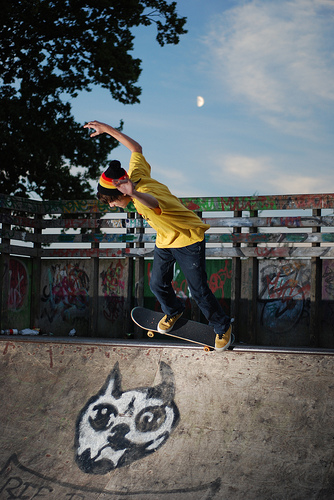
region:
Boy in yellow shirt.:
[66, 112, 253, 361]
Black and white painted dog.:
[67, 351, 201, 477]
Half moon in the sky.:
[152, 24, 287, 155]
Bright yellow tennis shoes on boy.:
[148, 293, 225, 345]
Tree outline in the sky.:
[0, 0, 186, 125]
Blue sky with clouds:
[200, 0, 324, 185]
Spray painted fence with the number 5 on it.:
[231, 174, 316, 341]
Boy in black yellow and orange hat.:
[89, 147, 137, 204]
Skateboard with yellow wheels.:
[120, 299, 151, 346]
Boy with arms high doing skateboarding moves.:
[68, 117, 247, 412]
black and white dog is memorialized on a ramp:
[69, 352, 197, 480]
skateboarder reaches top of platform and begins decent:
[74, 119, 263, 357]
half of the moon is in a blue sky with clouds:
[180, 78, 228, 140]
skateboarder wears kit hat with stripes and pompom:
[96, 148, 131, 210]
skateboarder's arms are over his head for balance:
[74, 103, 176, 238]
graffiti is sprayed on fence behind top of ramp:
[27, 185, 319, 312]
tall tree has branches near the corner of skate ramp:
[2, 13, 126, 225]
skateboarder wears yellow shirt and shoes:
[92, 138, 237, 357]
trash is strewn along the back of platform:
[0, 292, 142, 346]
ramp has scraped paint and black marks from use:
[35, 334, 293, 475]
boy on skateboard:
[80, 114, 240, 354]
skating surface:
[2, 341, 333, 498]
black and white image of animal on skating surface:
[67, 356, 183, 476]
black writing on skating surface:
[0, 452, 51, 496]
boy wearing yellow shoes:
[157, 310, 233, 351]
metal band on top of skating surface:
[0, 333, 333, 356]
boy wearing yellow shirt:
[128, 152, 208, 248]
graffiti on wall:
[5, 255, 333, 342]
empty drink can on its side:
[1, 325, 18, 337]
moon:
[194, 93, 206, 108]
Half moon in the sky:
[192, 89, 206, 107]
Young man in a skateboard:
[78, 113, 243, 356]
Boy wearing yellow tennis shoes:
[78, 110, 246, 359]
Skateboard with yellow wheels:
[127, 298, 241, 353]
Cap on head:
[87, 156, 139, 197]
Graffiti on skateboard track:
[60, 353, 192, 475]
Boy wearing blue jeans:
[78, 113, 238, 351]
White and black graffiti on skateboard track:
[71, 348, 182, 471]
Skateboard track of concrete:
[0, 196, 327, 497]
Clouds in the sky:
[219, 36, 332, 125]